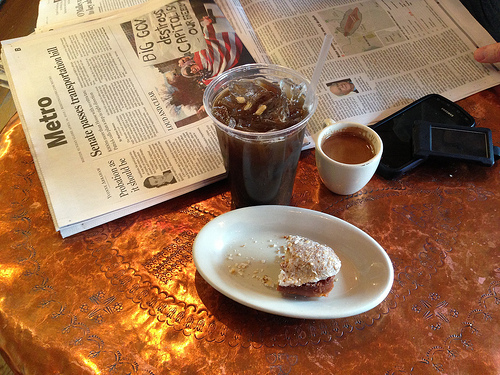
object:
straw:
[302, 33, 336, 113]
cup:
[200, 63, 319, 212]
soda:
[210, 75, 312, 210]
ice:
[211, 75, 308, 132]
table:
[3, 0, 499, 375]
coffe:
[321, 132, 378, 164]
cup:
[315, 116, 385, 198]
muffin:
[277, 234, 341, 298]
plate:
[191, 204, 393, 321]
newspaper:
[0, 0, 499, 241]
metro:
[37, 97, 69, 149]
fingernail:
[473, 47, 486, 62]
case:
[411, 119, 498, 168]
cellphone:
[367, 92, 477, 182]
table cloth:
[0, 87, 499, 374]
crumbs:
[260, 258, 267, 263]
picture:
[113, 0, 264, 129]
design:
[80, 286, 128, 327]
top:
[278, 235, 341, 286]